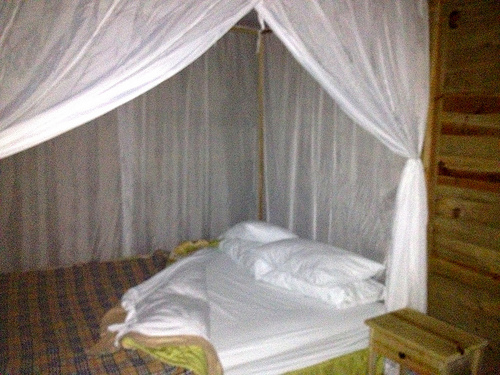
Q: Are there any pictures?
A: No, there are no pictures.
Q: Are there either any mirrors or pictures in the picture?
A: No, there are no pictures or mirrors.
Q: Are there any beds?
A: Yes, there is a bed.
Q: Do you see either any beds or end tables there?
A: Yes, there is a bed.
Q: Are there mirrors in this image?
A: No, there are no mirrors.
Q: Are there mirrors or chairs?
A: No, there are no mirrors or chairs.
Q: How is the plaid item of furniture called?
A: The piece of furniture is a bed.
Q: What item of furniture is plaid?
A: The piece of furniture is a bed.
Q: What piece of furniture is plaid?
A: The piece of furniture is a bed.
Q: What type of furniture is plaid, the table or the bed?
A: The bed is plaid.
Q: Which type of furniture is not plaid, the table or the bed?
A: The table is not plaid.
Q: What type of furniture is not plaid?
A: The furniture is a table.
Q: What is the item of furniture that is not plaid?
A: The piece of furniture is a table.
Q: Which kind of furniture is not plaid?
A: The furniture is a table.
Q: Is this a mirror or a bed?
A: This is a bed.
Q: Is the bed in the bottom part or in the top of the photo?
A: The bed is in the bottom of the image.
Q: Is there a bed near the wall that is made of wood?
A: Yes, there is a bed near the wall.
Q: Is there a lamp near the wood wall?
A: No, there is a bed near the wall.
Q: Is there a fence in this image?
A: No, there are no fences.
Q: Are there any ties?
A: Yes, there is a tie.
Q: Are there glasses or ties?
A: Yes, there is a tie.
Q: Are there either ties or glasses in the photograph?
A: Yes, there is a tie.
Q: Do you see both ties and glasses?
A: No, there is a tie but no glasses.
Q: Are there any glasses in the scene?
A: No, there are no glasses.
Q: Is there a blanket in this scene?
A: Yes, there is a blanket.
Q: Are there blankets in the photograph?
A: Yes, there is a blanket.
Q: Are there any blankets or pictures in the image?
A: Yes, there is a blanket.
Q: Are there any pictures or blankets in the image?
A: Yes, there is a blanket.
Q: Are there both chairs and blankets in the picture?
A: No, there is a blanket but no chairs.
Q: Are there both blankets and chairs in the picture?
A: No, there is a blanket but no chairs.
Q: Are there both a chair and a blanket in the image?
A: No, there is a blanket but no chairs.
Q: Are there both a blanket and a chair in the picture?
A: No, there is a blanket but no chairs.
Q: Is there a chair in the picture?
A: No, there are no chairs.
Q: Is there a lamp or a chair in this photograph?
A: No, there are no chairs or lamps.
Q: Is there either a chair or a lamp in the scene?
A: No, there are no chairs or lamps.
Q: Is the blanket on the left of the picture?
A: Yes, the blanket is on the left of the image.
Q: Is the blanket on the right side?
A: No, the blanket is on the left of the image.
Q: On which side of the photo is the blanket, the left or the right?
A: The blanket is on the left of the image.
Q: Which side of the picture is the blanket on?
A: The blanket is on the left of the image.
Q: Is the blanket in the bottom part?
A: Yes, the blanket is in the bottom of the image.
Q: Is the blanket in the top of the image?
A: No, the blanket is in the bottom of the image.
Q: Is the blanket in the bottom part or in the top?
A: The blanket is in the bottom of the image.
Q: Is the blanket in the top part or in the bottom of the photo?
A: The blanket is in the bottom of the image.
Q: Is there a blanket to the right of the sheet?
A: No, the blanket is to the left of the sheet.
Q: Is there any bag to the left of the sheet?
A: No, there is a blanket to the left of the sheet.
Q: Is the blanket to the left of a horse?
A: No, the blanket is to the left of the sheet.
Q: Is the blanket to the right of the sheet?
A: No, the blanket is to the left of the sheet.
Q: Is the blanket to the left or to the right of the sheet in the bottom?
A: The blanket is to the left of the sheet.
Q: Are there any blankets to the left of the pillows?
A: Yes, there is a blanket to the left of the pillows.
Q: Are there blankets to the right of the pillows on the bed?
A: No, the blanket is to the left of the pillows.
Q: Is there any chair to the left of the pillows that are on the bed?
A: No, there is a blanket to the left of the pillows.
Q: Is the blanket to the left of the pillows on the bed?
A: Yes, the blanket is to the left of the pillows.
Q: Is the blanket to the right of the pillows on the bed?
A: No, the blanket is to the left of the pillows.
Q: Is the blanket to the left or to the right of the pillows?
A: The blanket is to the left of the pillows.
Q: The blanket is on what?
A: The blanket is on the bed.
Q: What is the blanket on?
A: The blanket is on the bed.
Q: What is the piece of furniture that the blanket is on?
A: The piece of furniture is a bed.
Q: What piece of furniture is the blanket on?
A: The blanket is on the bed.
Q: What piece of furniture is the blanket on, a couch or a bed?
A: The blanket is on a bed.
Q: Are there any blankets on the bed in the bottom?
A: Yes, there is a blanket on the bed.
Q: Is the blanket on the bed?
A: Yes, the blanket is on the bed.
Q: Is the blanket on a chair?
A: No, the blanket is on the bed.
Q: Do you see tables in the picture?
A: Yes, there is a table.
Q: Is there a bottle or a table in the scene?
A: Yes, there is a table.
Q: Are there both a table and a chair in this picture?
A: No, there is a table but no chairs.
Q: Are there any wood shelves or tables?
A: Yes, there is a wood table.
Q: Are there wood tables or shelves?
A: Yes, there is a wood table.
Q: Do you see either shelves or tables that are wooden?
A: Yes, the table is wooden.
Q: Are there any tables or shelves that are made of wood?
A: Yes, the table is made of wood.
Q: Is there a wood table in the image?
A: Yes, there is a wood table.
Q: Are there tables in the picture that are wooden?
A: Yes, there is a table that is wooden.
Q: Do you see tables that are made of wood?
A: Yes, there is a table that is made of wood.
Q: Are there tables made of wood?
A: Yes, there is a table that is made of wood.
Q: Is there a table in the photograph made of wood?
A: Yes, there is a table that is made of wood.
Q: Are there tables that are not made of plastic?
A: Yes, there is a table that is made of wood.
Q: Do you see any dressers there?
A: No, there are no dressers.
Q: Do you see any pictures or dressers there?
A: No, there are no dressers or pictures.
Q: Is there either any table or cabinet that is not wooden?
A: No, there is a table but it is wooden.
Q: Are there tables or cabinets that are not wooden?
A: No, there is a table but it is wooden.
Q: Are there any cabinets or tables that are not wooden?
A: No, there is a table but it is wooden.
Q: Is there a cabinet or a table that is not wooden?
A: No, there is a table but it is wooden.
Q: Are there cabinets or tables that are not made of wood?
A: No, there is a table but it is made of wood.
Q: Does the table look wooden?
A: Yes, the table is wooden.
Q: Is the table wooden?
A: Yes, the table is wooden.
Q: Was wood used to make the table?
A: Yes, the table is made of wood.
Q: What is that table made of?
A: The table is made of wood.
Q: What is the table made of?
A: The table is made of wood.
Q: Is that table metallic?
A: No, the table is wooden.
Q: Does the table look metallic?
A: No, the table is wooden.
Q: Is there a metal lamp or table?
A: No, there is a table but it is wooden.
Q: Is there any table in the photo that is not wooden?
A: No, there is a table but it is wooden.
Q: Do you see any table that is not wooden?
A: No, there is a table but it is wooden.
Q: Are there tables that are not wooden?
A: No, there is a table but it is wooden.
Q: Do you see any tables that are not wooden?
A: No, there is a table but it is wooden.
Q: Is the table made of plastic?
A: No, the table is made of wood.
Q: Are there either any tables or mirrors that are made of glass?
A: No, there is a table but it is made of wood.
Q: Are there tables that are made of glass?
A: No, there is a table but it is made of wood.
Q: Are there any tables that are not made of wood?
A: No, there is a table but it is made of wood.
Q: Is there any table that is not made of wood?
A: No, there is a table but it is made of wood.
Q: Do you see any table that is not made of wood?
A: No, there is a table but it is made of wood.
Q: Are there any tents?
A: No, there are no tents.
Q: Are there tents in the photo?
A: No, there are no tents.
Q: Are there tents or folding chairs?
A: No, there are no tents or folding chairs.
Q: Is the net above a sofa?
A: No, the net is above the bed.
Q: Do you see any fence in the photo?
A: No, there are no fences.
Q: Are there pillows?
A: Yes, there are pillows.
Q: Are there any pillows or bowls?
A: Yes, there are pillows.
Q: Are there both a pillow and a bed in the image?
A: Yes, there are both a pillow and a bed.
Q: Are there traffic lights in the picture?
A: No, there are no traffic lights.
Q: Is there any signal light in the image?
A: No, there are no traffic lights.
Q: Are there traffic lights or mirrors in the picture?
A: No, there are no traffic lights or mirrors.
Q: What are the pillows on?
A: The pillows are on the bed.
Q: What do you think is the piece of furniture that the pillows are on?
A: The piece of furniture is a bed.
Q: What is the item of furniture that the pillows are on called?
A: The piece of furniture is a bed.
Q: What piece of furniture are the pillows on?
A: The pillows are on the bed.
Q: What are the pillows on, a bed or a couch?
A: The pillows are on a bed.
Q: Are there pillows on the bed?
A: Yes, there are pillows on the bed.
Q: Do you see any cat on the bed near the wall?
A: No, there are pillows on the bed.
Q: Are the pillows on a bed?
A: Yes, the pillows are on a bed.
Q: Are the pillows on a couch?
A: No, the pillows are on a bed.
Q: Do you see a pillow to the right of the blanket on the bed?
A: Yes, there are pillows to the right of the blanket.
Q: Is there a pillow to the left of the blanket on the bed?
A: No, the pillows are to the right of the blanket.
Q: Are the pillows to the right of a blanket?
A: Yes, the pillows are to the right of a blanket.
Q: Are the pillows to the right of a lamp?
A: No, the pillows are to the right of a blanket.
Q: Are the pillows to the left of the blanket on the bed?
A: No, the pillows are to the right of the blanket.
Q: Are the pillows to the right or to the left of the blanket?
A: The pillows are to the right of the blanket.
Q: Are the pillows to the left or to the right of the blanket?
A: The pillows are to the right of the blanket.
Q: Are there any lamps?
A: No, there are no lamps.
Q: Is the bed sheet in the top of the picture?
A: No, the bed sheet is in the bottom of the image.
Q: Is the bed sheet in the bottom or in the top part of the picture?
A: The bed sheet is in the bottom of the image.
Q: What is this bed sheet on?
A: The bed sheet is on the bed.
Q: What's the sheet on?
A: The bed sheet is on the bed.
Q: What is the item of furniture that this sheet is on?
A: The piece of furniture is a bed.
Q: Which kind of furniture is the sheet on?
A: The sheet is on the bed.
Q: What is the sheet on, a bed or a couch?
A: The sheet is on a bed.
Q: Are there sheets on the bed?
A: Yes, there is a sheet on the bed.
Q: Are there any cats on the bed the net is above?
A: No, there is a sheet on the bed.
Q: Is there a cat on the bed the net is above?
A: No, there is a sheet on the bed.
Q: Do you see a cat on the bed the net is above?
A: No, there is a sheet on the bed.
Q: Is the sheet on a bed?
A: Yes, the sheet is on a bed.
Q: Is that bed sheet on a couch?
A: No, the bed sheet is on a bed.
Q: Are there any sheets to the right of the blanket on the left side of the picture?
A: Yes, there is a sheet to the right of the blanket.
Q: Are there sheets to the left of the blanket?
A: No, the sheet is to the right of the blanket.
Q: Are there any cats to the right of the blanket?
A: No, there is a sheet to the right of the blanket.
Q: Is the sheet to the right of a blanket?
A: Yes, the sheet is to the right of a blanket.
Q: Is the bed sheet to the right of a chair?
A: No, the bed sheet is to the right of a blanket.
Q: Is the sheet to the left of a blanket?
A: No, the sheet is to the right of a blanket.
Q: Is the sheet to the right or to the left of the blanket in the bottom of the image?
A: The sheet is to the right of the blanket.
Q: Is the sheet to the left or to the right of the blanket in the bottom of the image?
A: The sheet is to the right of the blanket.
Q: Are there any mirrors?
A: No, there are no mirrors.